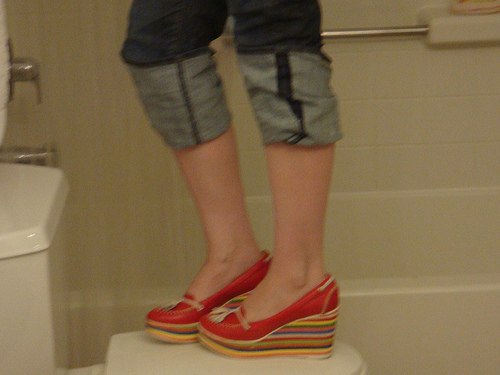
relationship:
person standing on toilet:
[119, 1, 342, 358] [0, 161, 370, 372]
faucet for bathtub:
[5, 127, 80, 199] [63, 186, 497, 375]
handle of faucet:
[5, 58, 44, 106] [5, 127, 80, 199]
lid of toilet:
[103, 328, 362, 373] [0, 161, 370, 372]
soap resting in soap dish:
[449, 1, 499, 16] [424, 7, 499, 48]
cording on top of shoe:
[207, 305, 239, 322] [198, 271, 340, 359]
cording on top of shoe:
[156, 297, 182, 309] [145, 252, 270, 336]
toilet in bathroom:
[0, 161, 369, 375] [1, 1, 481, 346]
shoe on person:
[197, 280, 335, 358] [119, 1, 342, 358]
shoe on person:
[143, 250, 273, 345] [119, 1, 342, 358]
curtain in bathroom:
[21, 0, 219, 360] [0, 1, 498, 373]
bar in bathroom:
[223, 25, 428, 43] [0, 1, 498, 373]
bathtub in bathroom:
[63, 186, 496, 373] [0, 1, 498, 373]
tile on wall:
[372, 92, 422, 149] [350, 56, 477, 330]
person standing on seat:
[119, 1, 342, 358] [105, 320, 365, 375]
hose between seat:
[64, 364, 101, 372] [93, 271, 401, 373]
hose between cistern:
[64, 364, 101, 372] [2, 160, 73, 372]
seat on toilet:
[111, 303, 362, 373] [0, 161, 370, 372]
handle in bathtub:
[5, 58, 44, 106] [8, 30, 50, 105]